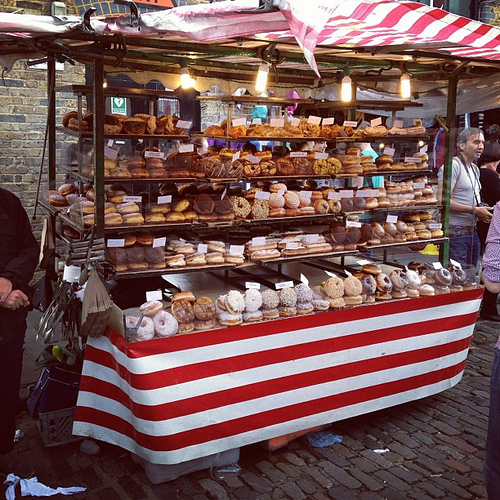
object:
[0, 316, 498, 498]
floor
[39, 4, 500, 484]
kiosk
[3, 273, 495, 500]
sidewalk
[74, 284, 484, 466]
skirt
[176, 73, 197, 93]
lights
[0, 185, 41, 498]
person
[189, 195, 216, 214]
doughnuts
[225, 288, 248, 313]
doughnuts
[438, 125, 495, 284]
man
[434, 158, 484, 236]
shirt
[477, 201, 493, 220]
camera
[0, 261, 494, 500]
street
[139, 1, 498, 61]
fabric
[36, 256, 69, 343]
tools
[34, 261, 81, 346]
grabbing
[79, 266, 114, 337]
bags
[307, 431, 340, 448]
trash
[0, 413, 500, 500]
ground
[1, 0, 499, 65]
covering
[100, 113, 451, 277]
shelves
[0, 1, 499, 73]
awning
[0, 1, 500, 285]
building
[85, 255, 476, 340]
table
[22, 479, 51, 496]
litter